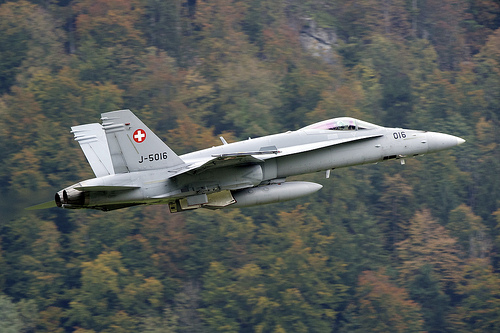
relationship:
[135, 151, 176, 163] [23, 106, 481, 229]
number on jet